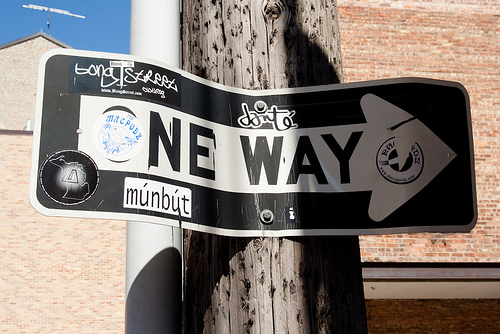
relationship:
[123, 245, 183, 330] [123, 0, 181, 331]
shadow on pole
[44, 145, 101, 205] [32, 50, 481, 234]
sticker on sign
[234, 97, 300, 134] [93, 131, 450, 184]
graffiti above arrow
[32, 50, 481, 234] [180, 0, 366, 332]
sign attached to pole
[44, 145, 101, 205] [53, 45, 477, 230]
sticker on sign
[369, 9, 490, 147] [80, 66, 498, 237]
wall behind sign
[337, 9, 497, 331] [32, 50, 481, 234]
building on right side of sign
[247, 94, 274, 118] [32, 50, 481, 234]
screws attaching sign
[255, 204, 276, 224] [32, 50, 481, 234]
screws attaching sign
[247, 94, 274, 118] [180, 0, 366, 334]
screws attaching sign to pole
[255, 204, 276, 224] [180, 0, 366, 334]
screws attaching sign to pole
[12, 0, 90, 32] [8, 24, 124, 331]
antenna on top of building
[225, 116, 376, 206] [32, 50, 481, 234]
word on sign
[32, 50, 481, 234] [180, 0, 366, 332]
sign on pole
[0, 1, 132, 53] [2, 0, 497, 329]
blue sky above building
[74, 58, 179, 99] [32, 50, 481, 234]
graffiti on sign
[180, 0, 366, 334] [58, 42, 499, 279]
pole behind sign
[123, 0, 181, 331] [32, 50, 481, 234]
pole behind sign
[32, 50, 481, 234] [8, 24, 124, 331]
sign on left of building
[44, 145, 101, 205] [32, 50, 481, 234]
sticker on corner of sign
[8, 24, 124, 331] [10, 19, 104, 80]
building with roof.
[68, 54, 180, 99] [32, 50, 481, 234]
graffiti on sign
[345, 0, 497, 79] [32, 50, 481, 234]
brick wall behind sign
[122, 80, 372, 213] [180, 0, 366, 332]
sign on pole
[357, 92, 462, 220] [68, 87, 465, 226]
tip of arrow